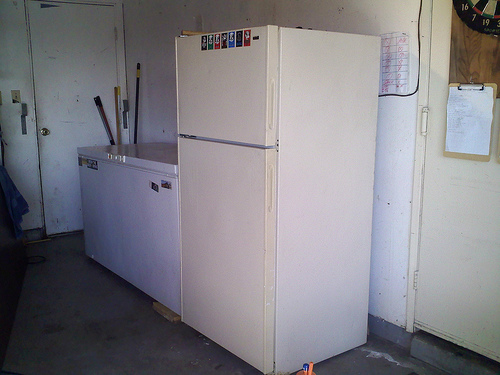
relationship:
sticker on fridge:
[241, 25, 252, 49] [167, 22, 382, 372]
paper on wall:
[358, 48, 445, 100] [377, 135, 474, 280]